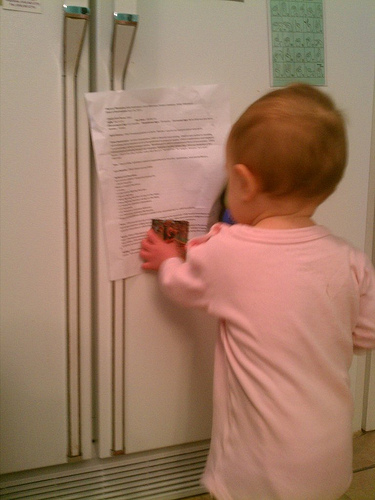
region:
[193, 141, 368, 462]
The baby is standing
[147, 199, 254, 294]
The baby is touching the wall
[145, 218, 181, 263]
The baby has a picture in her hand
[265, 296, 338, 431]
The baby gown is pink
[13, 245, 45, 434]
The wall is white.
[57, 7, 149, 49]
The refrigerator door handles.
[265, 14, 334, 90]
A green calendar on the wall.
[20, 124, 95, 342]
The refrigerator is white.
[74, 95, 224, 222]
A paper on the refrigerator.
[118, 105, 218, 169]
The paper has black writing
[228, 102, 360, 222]
A baby with blonde hair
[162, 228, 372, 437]
Baby wearing pink outfit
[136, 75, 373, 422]
Baby girl playing with magnet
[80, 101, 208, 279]
A paper hung on the fridge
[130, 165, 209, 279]
A magnet hanging on the fridge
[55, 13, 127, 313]
Fridge door handles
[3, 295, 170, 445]
White colored fridge door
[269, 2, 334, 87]
Green poster on front of fridge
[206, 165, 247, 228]
Baby has pacifier in her mouth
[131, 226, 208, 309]
Babies tiny hand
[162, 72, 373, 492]
small very young child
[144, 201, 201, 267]
magnet holding paper on fridge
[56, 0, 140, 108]
two door handles of fridge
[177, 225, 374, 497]
white t-shirt worn by small child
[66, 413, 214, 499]
vents along bottom of fridge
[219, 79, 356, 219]
small child with light brown hair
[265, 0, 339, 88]
green magnet on fridge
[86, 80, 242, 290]
white paper with black writing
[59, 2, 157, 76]
gold green and white fridge handles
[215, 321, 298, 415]
wrinkles in white t-shirt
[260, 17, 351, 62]
Pictures are stick to the wall.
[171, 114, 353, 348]
One baby is seen.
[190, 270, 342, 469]
Baby is in white dress.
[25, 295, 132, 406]
Walls are white color.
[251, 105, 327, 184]
Hair is blonde color.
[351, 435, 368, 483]
Floor is brown color.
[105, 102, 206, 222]
Letters are black color.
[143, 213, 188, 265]
Baby is holding a picture.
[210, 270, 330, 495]
Baby is standing in floor.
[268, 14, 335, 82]
Picture is blue color.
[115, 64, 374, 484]
A baby in a pink outfit.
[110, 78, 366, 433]
The baby is playing with a refrigerator magnet.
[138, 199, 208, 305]
The refrigerator magnet is square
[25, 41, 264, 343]
The magnet is holding up a piece of paper.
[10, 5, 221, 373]
The paper is on the door of a refrigerator.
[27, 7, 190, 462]
The refrigerator is a side-by-side refrigerator.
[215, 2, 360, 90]
Another paper is on the front of the refrigerator.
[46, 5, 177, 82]
The refrigerator has green trim on the doors.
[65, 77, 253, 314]
The piece of paper the magnet is holding up has typewritten things on it.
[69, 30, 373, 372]
The baby's outfit has snaps on the shoulder.